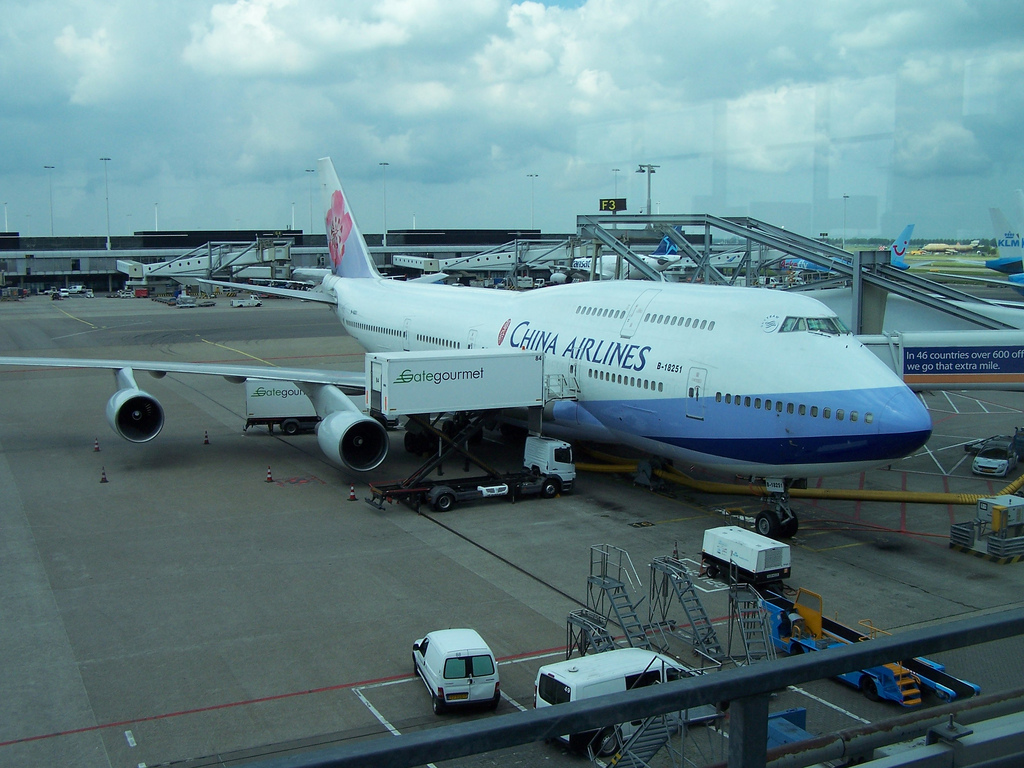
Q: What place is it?
A: It is an airport.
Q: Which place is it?
A: It is an airport.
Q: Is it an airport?
A: Yes, it is an airport.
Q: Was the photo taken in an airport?
A: Yes, it was taken in an airport.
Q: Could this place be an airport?
A: Yes, it is an airport.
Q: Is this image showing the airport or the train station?
A: It is showing the airport.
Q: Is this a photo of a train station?
A: No, the picture is showing an airport.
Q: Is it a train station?
A: No, it is an airport.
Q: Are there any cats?
A: No, there are no cats.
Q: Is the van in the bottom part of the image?
A: Yes, the van is in the bottom of the image.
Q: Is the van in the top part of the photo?
A: No, the van is in the bottom of the image.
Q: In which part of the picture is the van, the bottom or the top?
A: The van is in the bottom of the image.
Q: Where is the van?
A: The van is at the airport.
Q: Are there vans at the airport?
A: Yes, there is a van at the airport.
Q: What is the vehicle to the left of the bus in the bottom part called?
A: The vehicle is a van.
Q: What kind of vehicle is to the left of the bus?
A: The vehicle is a van.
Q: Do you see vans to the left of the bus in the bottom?
A: Yes, there is a van to the left of the bus.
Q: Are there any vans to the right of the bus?
A: No, the van is to the left of the bus.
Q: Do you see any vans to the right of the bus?
A: No, the van is to the left of the bus.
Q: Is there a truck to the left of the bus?
A: No, there is a van to the left of the bus.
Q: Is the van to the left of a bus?
A: Yes, the van is to the left of a bus.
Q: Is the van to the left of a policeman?
A: No, the van is to the left of a bus.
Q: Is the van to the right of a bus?
A: No, the van is to the left of a bus.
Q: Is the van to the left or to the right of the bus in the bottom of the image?
A: The van is to the left of the bus.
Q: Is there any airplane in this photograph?
A: Yes, there is an airplane.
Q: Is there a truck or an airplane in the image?
A: Yes, there is an airplane.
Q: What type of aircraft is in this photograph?
A: The aircraft is an airplane.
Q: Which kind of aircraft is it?
A: The aircraft is an airplane.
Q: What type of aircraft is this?
A: That is an airplane.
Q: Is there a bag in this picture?
A: No, there are no bags.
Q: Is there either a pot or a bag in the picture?
A: No, there are no bags or pots.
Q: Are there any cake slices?
A: No, there are no cake slices.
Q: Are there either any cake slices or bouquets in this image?
A: No, there are no cake slices or bouquets.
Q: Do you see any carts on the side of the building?
A: Yes, there is a cart on the side of the building.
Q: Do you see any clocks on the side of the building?
A: No, there is a cart on the side of the building.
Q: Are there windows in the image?
A: Yes, there is a window.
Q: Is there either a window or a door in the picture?
A: Yes, there is a window.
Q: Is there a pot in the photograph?
A: No, there are no pots.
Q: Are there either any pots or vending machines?
A: No, there are no pots or vending machines.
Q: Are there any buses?
A: Yes, there is a bus.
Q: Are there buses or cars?
A: Yes, there is a bus.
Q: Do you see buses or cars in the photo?
A: Yes, there is a bus.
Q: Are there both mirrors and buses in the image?
A: No, there is a bus but no mirrors.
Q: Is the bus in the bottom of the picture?
A: Yes, the bus is in the bottom of the image.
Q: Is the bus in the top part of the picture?
A: No, the bus is in the bottom of the image.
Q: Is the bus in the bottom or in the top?
A: The bus is in the bottom of the image.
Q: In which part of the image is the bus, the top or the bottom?
A: The bus is in the bottom of the image.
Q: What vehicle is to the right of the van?
A: The vehicle is a bus.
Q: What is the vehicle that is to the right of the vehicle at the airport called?
A: The vehicle is a bus.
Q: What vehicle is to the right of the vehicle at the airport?
A: The vehicle is a bus.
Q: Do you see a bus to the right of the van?
A: Yes, there is a bus to the right of the van.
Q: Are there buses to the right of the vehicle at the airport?
A: Yes, there is a bus to the right of the van.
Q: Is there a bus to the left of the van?
A: No, the bus is to the right of the van.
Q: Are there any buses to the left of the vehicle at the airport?
A: No, the bus is to the right of the van.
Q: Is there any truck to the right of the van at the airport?
A: No, there is a bus to the right of the van.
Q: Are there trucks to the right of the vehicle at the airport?
A: No, there is a bus to the right of the van.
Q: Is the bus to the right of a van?
A: Yes, the bus is to the right of a van.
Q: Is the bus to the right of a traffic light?
A: No, the bus is to the right of a van.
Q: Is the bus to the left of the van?
A: No, the bus is to the right of the van.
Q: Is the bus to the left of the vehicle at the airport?
A: No, the bus is to the right of the van.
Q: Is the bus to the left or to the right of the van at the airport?
A: The bus is to the right of the van.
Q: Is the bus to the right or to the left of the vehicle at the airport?
A: The bus is to the right of the van.